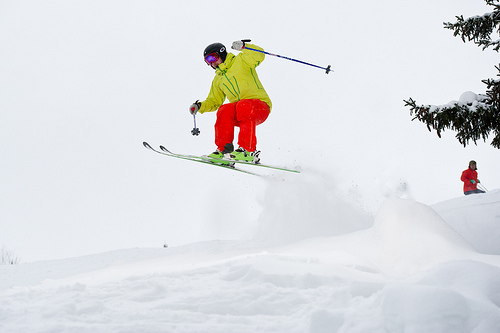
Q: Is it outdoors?
A: Yes, it is outdoors.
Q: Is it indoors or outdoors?
A: It is outdoors.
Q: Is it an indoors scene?
A: No, it is outdoors.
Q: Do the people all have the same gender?
A: No, they are both male and female.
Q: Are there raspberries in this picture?
A: No, there are no raspberries.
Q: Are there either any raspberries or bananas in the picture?
A: No, there are no raspberries or bananas.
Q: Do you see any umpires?
A: No, there are no umpires.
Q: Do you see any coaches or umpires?
A: No, there are no umpires or coaches.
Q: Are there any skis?
A: Yes, there are skis.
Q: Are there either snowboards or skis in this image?
A: Yes, there are skis.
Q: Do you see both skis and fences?
A: No, there are skis but no fences.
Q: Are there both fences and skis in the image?
A: No, there are skis but no fences.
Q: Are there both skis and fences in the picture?
A: No, there are skis but no fences.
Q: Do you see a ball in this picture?
A: No, there are no balls.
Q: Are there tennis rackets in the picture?
A: No, there are no tennis rackets.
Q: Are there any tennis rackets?
A: No, there are no tennis rackets.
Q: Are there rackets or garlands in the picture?
A: No, there are no rackets or garlands.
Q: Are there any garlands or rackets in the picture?
A: No, there are no rackets or garlands.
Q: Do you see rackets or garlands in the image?
A: No, there are no rackets or garlands.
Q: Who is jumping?
A: The man is jumping.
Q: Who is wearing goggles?
A: The man is wearing goggles.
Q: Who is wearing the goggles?
A: The man is wearing goggles.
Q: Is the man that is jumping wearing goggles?
A: Yes, the man is wearing goggles.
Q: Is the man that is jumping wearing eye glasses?
A: No, the man is wearing goggles.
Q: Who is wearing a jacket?
A: The man is wearing a jacket.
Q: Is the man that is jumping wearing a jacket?
A: Yes, the man is wearing a jacket.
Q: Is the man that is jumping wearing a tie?
A: No, the man is wearing a jacket.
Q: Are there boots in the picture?
A: Yes, there are boots.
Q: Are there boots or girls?
A: Yes, there are boots.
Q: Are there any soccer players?
A: No, there are no soccer players.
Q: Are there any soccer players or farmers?
A: No, there are no soccer players or farmers.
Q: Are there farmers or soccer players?
A: No, there are no soccer players or farmers.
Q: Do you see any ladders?
A: No, there are no ladders.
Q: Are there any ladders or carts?
A: No, there are no ladders or carts.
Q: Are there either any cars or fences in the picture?
A: No, there are no fences or cars.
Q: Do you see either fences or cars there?
A: No, there are no fences or cars.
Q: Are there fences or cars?
A: No, there are no fences or cars.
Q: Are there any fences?
A: No, there are no fences.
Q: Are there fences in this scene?
A: No, there are no fences.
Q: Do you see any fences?
A: No, there are no fences.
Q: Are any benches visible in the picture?
A: No, there are no benches.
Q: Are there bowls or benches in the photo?
A: No, there are no benches or bowls.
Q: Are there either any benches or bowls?
A: No, there are no benches or bowls.